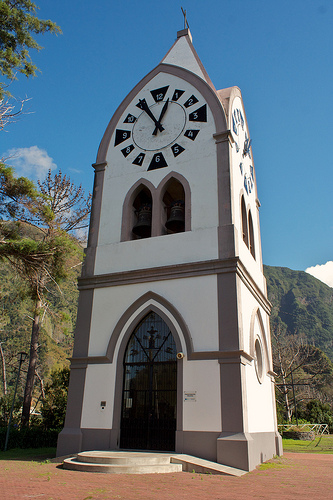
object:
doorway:
[117, 309, 180, 455]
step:
[61, 448, 183, 476]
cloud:
[303, 261, 333, 289]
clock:
[229, 106, 255, 196]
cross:
[172, 0, 191, 36]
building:
[55, 5, 283, 472]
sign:
[183, 390, 196, 403]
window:
[253, 333, 267, 386]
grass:
[0, 431, 333, 473]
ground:
[0, 433, 333, 499]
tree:
[0, 0, 95, 464]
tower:
[56, 0, 285, 471]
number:
[156, 93, 163, 101]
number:
[175, 92, 179, 99]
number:
[188, 98, 194, 106]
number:
[193, 112, 199, 120]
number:
[155, 155, 160, 163]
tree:
[271, 327, 306, 423]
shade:
[0, 430, 57, 462]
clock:
[113, 82, 208, 173]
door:
[112, 307, 178, 451]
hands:
[134, 95, 172, 137]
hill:
[263, 263, 333, 352]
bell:
[164, 199, 187, 234]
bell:
[132, 197, 151, 237]